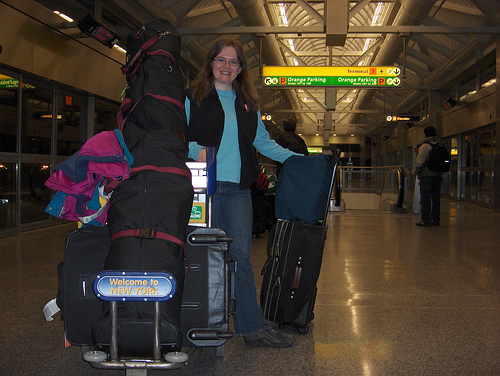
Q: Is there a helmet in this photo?
A: No, there are no helmets.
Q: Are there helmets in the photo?
A: No, there are no helmets.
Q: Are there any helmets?
A: No, there are no helmets.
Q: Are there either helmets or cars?
A: No, there are no helmets or cars.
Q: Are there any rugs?
A: No, there are no rugs.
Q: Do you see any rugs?
A: No, there are no rugs.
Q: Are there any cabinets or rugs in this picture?
A: No, there are no rugs or cabinets.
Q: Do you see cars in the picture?
A: No, there are no cars.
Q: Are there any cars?
A: No, there are no cars.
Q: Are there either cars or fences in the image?
A: No, there are no cars or fences.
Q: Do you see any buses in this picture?
A: No, there are no buses.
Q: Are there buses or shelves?
A: No, there are no buses or shelves.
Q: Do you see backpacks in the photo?
A: Yes, there is a backpack.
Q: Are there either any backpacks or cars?
A: Yes, there is a backpack.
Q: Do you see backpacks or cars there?
A: Yes, there is a backpack.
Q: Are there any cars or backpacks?
A: Yes, there is a backpack.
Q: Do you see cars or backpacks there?
A: Yes, there is a backpack.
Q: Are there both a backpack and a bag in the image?
A: Yes, there are both a backpack and a bag.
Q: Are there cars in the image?
A: No, there are no cars.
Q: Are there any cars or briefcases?
A: No, there are no cars or briefcases.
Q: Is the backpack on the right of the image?
A: Yes, the backpack is on the right of the image.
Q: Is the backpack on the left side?
A: No, the backpack is on the right of the image.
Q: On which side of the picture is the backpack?
A: The backpack is on the right of the image.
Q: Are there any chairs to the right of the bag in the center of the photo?
A: No, there is a backpack to the right of the bag.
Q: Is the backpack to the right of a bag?
A: Yes, the backpack is to the right of a bag.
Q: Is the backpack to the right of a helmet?
A: No, the backpack is to the right of a bag.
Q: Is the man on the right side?
A: Yes, the man is on the right of the image.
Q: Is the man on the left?
A: No, the man is on the right of the image.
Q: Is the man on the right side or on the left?
A: The man is on the right of the image.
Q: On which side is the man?
A: The man is on the right of the image.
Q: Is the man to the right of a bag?
A: Yes, the man is to the right of a bag.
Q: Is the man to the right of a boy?
A: No, the man is to the right of a bag.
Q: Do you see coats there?
A: Yes, there is a coat.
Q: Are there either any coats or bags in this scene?
A: Yes, there is a coat.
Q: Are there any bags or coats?
A: Yes, there is a coat.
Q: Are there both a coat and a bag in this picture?
A: Yes, there are both a coat and a bag.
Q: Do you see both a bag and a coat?
A: Yes, there are both a coat and a bag.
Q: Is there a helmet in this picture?
A: No, there are no helmets.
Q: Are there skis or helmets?
A: No, there are no helmets or skis.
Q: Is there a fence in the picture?
A: No, there are no fences.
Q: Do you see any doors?
A: Yes, there is a door.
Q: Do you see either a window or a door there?
A: Yes, there is a door.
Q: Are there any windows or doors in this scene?
A: Yes, there is a door.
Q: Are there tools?
A: No, there are no tools.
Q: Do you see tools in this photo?
A: No, there are no tools.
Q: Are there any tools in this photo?
A: No, there are no tools.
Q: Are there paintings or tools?
A: No, there are no tools or paintings.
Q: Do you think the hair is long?
A: Yes, the hair is long.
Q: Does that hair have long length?
A: Yes, the hair is long.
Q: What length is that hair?
A: The hair is long.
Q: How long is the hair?
A: The hair is long.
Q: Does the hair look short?
A: No, the hair is long.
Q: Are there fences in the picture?
A: No, there are no fences.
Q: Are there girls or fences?
A: No, there are no fences or girls.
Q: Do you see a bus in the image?
A: No, there are no buses.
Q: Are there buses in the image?
A: No, there are no buses.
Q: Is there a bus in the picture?
A: No, there are no buses.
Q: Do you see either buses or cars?
A: No, there are no buses or cars.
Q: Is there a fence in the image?
A: No, there are no fences.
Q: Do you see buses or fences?
A: No, there are no fences or buses.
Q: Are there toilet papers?
A: No, there are no toilet papers.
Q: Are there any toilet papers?
A: No, there are no toilet papers.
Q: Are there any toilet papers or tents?
A: No, there are no toilet papers or tents.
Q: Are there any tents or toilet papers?
A: No, there are no toilet papers or tents.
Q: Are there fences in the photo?
A: No, there are no fences.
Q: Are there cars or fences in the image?
A: No, there are no fences or cars.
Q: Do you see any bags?
A: Yes, there is a bag.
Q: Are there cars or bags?
A: Yes, there is a bag.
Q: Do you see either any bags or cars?
A: Yes, there is a bag.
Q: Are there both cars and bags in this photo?
A: No, there is a bag but no cars.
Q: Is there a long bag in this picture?
A: Yes, there is a long bag.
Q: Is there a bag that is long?
A: Yes, there is a bag that is long.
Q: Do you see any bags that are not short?
A: Yes, there is a long bag.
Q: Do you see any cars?
A: No, there are no cars.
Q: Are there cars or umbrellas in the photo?
A: No, there are no cars or umbrellas.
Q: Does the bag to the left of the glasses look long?
A: Yes, the bag is long.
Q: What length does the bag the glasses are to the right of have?
A: The bag has long length.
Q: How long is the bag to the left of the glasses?
A: The bag is long.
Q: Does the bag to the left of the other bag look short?
A: No, the bag is long.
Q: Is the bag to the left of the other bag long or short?
A: The bag is long.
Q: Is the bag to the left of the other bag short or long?
A: The bag is long.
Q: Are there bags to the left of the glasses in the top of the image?
A: Yes, there is a bag to the left of the glasses.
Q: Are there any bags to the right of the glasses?
A: No, the bag is to the left of the glasses.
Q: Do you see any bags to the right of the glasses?
A: No, the bag is to the left of the glasses.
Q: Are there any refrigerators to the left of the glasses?
A: No, there is a bag to the left of the glasses.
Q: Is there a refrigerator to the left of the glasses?
A: No, there is a bag to the left of the glasses.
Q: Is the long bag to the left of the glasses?
A: Yes, the bag is to the left of the glasses.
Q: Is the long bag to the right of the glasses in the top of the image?
A: No, the bag is to the left of the glasses.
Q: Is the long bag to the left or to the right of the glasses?
A: The bag is to the left of the glasses.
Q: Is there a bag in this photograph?
A: Yes, there is a bag.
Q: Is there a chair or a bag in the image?
A: Yes, there is a bag.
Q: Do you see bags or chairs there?
A: Yes, there is a bag.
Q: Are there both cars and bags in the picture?
A: No, there is a bag but no cars.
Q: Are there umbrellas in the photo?
A: No, there are no umbrellas.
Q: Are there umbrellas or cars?
A: No, there are no umbrellas or cars.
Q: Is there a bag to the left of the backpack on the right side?
A: Yes, there is a bag to the left of the backpack.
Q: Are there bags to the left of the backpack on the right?
A: Yes, there is a bag to the left of the backpack.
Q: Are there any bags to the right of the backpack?
A: No, the bag is to the left of the backpack.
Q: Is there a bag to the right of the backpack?
A: No, the bag is to the left of the backpack.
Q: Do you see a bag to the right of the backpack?
A: No, the bag is to the left of the backpack.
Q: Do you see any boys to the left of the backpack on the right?
A: No, there is a bag to the left of the backpack.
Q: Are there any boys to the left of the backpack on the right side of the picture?
A: No, there is a bag to the left of the backpack.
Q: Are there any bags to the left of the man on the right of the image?
A: Yes, there is a bag to the left of the man.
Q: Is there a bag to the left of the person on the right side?
A: Yes, there is a bag to the left of the man.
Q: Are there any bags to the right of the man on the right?
A: No, the bag is to the left of the man.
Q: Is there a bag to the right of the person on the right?
A: No, the bag is to the left of the man.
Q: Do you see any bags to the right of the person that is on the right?
A: No, the bag is to the left of the man.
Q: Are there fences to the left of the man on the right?
A: No, there is a bag to the left of the man.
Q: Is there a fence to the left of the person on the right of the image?
A: No, there is a bag to the left of the man.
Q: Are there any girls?
A: No, there are no girls.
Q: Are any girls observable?
A: No, there are no girls.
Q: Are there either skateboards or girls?
A: No, there are no girls or skateboards.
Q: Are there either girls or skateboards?
A: No, there are no girls or skateboards.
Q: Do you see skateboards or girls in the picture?
A: No, there are no girls or skateboards.